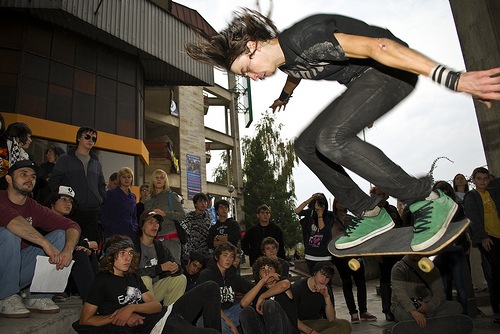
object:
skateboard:
[390, 314, 474, 334]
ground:
[24, 316, 79, 333]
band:
[99, 240, 135, 261]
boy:
[290, 261, 352, 333]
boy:
[239, 256, 296, 334]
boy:
[191, 242, 256, 334]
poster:
[186, 153, 203, 200]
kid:
[461, 166, 499, 325]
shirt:
[475, 188, 500, 238]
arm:
[323, 33, 456, 89]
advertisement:
[186, 153, 202, 200]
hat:
[50, 184, 79, 206]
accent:
[0, 113, 152, 166]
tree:
[211, 110, 305, 256]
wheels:
[348, 258, 361, 271]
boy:
[48, 127, 106, 245]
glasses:
[84, 134, 97, 142]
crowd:
[0, 118, 500, 334]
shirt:
[0, 189, 81, 249]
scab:
[379, 44, 386, 49]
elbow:
[369, 36, 402, 58]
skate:
[328, 218, 471, 273]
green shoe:
[334, 207, 396, 250]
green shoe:
[409, 189, 459, 252]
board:
[327, 218, 471, 273]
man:
[0, 160, 82, 318]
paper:
[29, 255, 75, 293]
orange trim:
[0, 109, 150, 166]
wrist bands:
[279, 90, 294, 102]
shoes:
[350, 313, 360, 323]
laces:
[412, 201, 434, 233]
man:
[132, 210, 187, 314]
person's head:
[139, 215, 160, 237]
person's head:
[76, 126, 98, 149]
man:
[174, 0, 500, 252]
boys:
[171, 251, 207, 293]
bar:
[0, 111, 151, 164]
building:
[0, 0, 253, 233]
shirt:
[278, 14, 410, 85]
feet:
[333, 207, 396, 250]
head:
[224, 32, 278, 81]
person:
[77, 234, 222, 333]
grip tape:
[376, 237, 411, 251]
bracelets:
[428, 64, 462, 92]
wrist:
[446, 65, 460, 93]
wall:
[178, 84, 208, 155]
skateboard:
[327, 217, 470, 273]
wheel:
[418, 257, 435, 273]